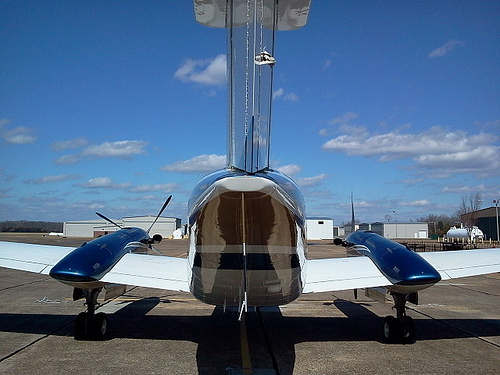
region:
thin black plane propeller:
[85, 189, 172, 254]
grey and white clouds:
[315, 98, 492, 195]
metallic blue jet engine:
[346, 223, 451, 298]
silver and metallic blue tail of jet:
[189, 2, 309, 342]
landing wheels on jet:
[379, 314, 416, 347]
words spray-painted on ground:
[14, 291, 79, 309]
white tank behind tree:
[442, 220, 480, 242]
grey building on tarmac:
[51, 214, 186, 239]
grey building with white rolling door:
[338, 220, 430, 242]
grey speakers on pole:
[486, 197, 498, 243]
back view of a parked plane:
[9, 4, 499, 369]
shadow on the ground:
[144, 307, 370, 373]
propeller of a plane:
[87, 199, 181, 228]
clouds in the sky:
[324, 116, 499, 185]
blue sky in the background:
[5, 10, 175, 116]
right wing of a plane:
[306, 247, 498, 307]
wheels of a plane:
[372, 310, 424, 351]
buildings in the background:
[359, 217, 440, 242]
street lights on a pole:
[486, 195, 498, 247]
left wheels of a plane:
[72, 306, 119, 348]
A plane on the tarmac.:
[0, 0, 497, 365]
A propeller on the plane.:
[80, 180, 180, 275]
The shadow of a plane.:
[0, 280, 480, 370]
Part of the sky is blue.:
[16, 10, 156, 80]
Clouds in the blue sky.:
[46, 90, 191, 175]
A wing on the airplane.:
[295, 220, 495, 345]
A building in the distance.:
[50, 200, 180, 245]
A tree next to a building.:
[450, 185, 490, 245]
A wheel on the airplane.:
[375, 310, 418, 356]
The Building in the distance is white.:
[307, 215, 337, 247]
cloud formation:
[321, 108, 499, 179]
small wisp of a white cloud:
[422, 34, 467, 64]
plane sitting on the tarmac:
[2, 1, 499, 346]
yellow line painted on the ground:
[231, 312, 256, 373]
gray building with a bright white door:
[363, 217, 437, 241]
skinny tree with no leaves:
[449, 194, 480, 232]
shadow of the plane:
[1, 286, 498, 373]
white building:
[299, 211, 339, 242]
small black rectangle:
[315, 220, 326, 225]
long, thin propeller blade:
[145, 188, 177, 236]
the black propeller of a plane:
[91, 192, 175, 255]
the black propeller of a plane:
[334, 188, 374, 247]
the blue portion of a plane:
[50, 223, 150, 288]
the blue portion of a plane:
[343, 224, 435, 291]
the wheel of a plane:
[78, 311, 93, 338]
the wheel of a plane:
[91, 311, 108, 338]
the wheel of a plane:
[381, 310, 401, 347]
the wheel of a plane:
[400, 316, 422, 350]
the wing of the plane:
[0, 237, 193, 299]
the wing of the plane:
[304, 243, 497, 290]